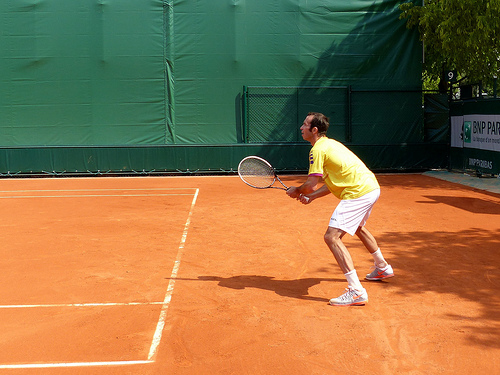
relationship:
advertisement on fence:
[447, 114, 500, 153] [237, 84, 500, 177]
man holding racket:
[281, 108, 400, 308] [233, 153, 311, 201]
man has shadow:
[281, 108, 400, 308] [174, 270, 373, 313]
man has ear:
[281, 108, 400, 308] [311, 127, 319, 135]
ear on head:
[311, 127, 319, 135] [295, 108, 329, 145]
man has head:
[281, 108, 400, 308] [295, 108, 329, 145]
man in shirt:
[281, 108, 400, 308] [305, 135, 383, 201]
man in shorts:
[281, 108, 400, 308] [326, 185, 383, 240]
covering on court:
[1, 1, 435, 176] [0, 172, 499, 375]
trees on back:
[394, 0, 499, 97] [339, 149, 500, 374]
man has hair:
[281, 108, 400, 308] [308, 111, 334, 136]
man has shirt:
[281, 108, 400, 308] [305, 135, 383, 201]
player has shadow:
[229, 99, 400, 320] [174, 270, 373, 313]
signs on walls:
[449, 111, 500, 183] [422, 81, 498, 200]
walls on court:
[422, 81, 498, 200] [0, 172, 499, 375]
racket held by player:
[233, 153, 311, 201] [229, 99, 400, 320]